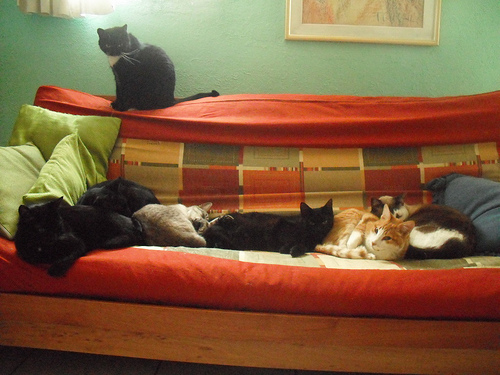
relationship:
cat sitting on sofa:
[86, 18, 219, 117] [0, 84, 500, 375]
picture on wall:
[282, 1, 446, 49] [195, 2, 280, 78]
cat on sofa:
[96, 23, 221, 112] [0, 84, 500, 375]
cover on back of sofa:
[34, 83, 497, 139] [0, 84, 500, 375]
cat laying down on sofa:
[314, 201, 415, 260] [0, 84, 500, 375]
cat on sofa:
[96, 23, 221, 112] [0, 82, 498, 370]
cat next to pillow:
[96, 23, 221, 112] [22, 131, 96, 205]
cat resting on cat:
[76, 175, 158, 215] [96, 23, 221, 112]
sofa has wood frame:
[0, 82, 498, 370] [0, 289, 498, 373]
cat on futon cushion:
[96, 23, 221, 112] [0, 237, 498, 320]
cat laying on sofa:
[96, 23, 221, 112] [0, 84, 500, 375]